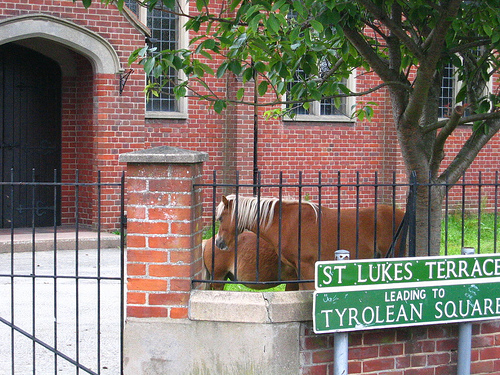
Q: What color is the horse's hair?
A: White.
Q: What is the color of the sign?
A: Green.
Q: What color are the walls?
A: Red.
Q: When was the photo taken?
A: Daytime.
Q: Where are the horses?
A: In the lawn.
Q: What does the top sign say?
A: ST LUKES TERRACE.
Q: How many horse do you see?
A: Two.